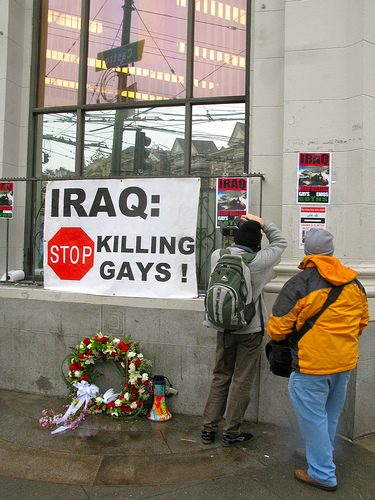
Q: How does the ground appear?
A: Wet.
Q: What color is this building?
A: Gray.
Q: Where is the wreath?
A: In front of building.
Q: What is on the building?
A: Signs.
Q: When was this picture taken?
A: In the daytime.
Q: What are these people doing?
A: Photographing.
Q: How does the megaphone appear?
A: Colorful.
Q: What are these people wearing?
A: Hats.